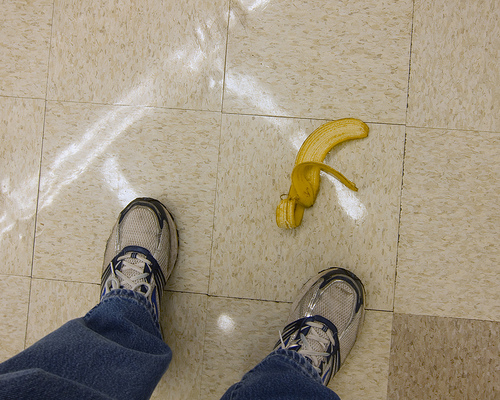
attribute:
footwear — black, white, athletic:
[82, 196, 378, 388]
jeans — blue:
[41, 279, 313, 399]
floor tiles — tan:
[21, 23, 499, 302]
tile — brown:
[385, 310, 497, 398]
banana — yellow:
[275, 116, 368, 232]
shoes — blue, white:
[97, 197, 366, 387]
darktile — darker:
[386, 314, 498, 399]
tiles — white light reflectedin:
[137, 44, 297, 171]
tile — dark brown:
[383, 312, 498, 392]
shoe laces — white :
[102, 253, 332, 375]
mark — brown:
[304, 186, 311, 206]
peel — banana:
[276, 116, 366, 228]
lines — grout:
[390, 0, 411, 315]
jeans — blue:
[0, 286, 339, 398]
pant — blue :
[48, 234, 388, 392]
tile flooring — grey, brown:
[2, 1, 494, 395]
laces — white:
[294, 315, 340, 372]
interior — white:
[305, 127, 335, 160]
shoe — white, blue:
[267, 268, 365, 385]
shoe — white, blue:
[95, 193, 178, 322]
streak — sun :
[226, 70, 363, 218]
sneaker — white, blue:
[277, 264, 365, 384]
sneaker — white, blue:
[98, 199, 182, 320]